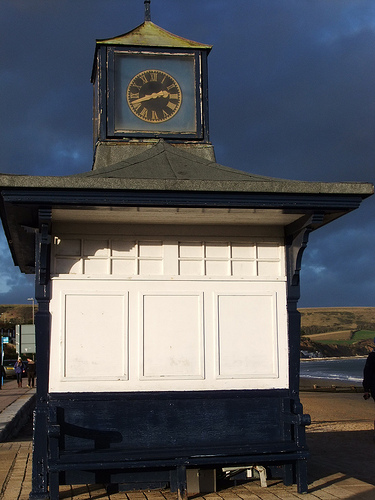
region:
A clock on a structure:
[85, 37, 235, 138]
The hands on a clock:
[130, 80, 171, 103]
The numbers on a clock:
[130, 64, 167, 84]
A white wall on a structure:
[43, 257, 290, 400]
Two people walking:
[12, 352, 34, 384]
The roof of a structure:
[2, 138, 368, 245]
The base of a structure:
[10, 399, 326, 485]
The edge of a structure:
[281, 261, 311, 400]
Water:
[308, 349, 357, 390]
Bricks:
[5, 436, 30, 492]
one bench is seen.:
[31, 398, 325, 495]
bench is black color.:
[40, 398, 309, 474]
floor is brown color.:
[259, 484, 335, 499]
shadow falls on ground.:
[316, 420, 373, 495]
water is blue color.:
[312, 362, 361, 377]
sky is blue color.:
[254, 85, 341, 141]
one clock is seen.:
[125, 67, 199, 124]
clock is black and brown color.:
[112, 59, 198, 134]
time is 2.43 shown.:
[127, 69, 181, 123]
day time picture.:
[19, 29, 365, 488]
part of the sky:
[283, 90, 326, 134]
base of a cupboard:
[227, 455, 251, 466]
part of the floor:
[323, 461, 344, 491]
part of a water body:
[324, 353, 340, 369]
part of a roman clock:
[152, 92, 178, 115]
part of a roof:
[231, 169, 271, 185]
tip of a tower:
[140, 2, 155, 18]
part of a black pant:
[13, 363, 25, 388]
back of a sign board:
[20, 333, 31, 347]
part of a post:
[28, 299, 36, 312]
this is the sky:
[237, 58, 366, 111]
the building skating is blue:
[55, 393, 303, 460]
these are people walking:
[12, 355, 37, 384]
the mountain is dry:
[314, 304, 369, 328]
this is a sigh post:
[1, 336, 10, 354]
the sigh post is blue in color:
[0, 333, 12, 362]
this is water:
[319, 363, 364, 379]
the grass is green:
[356, 328, 371, 337]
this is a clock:
[122, 63, 193, 125]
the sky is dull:
[11, 18, 89, 108]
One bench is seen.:
[48, 397, 285, 479]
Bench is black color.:
[55, 395, 287, 475]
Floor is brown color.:
[247, 486, 288, 496]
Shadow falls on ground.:
[238, 426, 358, 496]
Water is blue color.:
[316, 357, 358, 378]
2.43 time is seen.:
[127, 70, 174, 119]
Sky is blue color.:
[236, 21, 324, 126]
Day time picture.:
[23, 90, 283, 474]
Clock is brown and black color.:
[126, 69, 189, 138]